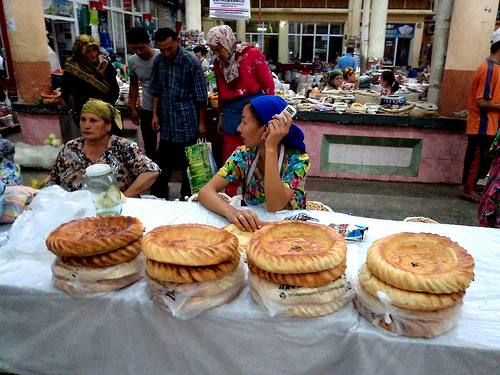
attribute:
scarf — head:
[254, 153, 305, 183]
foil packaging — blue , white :
[282, 97, 398, 149]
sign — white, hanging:
[207, 0, 249, 20]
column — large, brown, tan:
[12, 0, 91, 115]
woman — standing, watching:
[60, 35, 120, 137]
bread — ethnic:
[48, 217, 474, 340]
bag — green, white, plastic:
[175, 65, 198, 109]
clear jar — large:
[84, 164, 123, 216]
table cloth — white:
[1, 182, 498, 372]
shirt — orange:
[462, 62, 499, 144]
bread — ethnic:
[140, 222, 240, 266]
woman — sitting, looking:
[36, 95, 168, 197]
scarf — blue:
[248, 91, 313, 135]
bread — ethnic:
[44, 212, 146, 294]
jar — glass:
[80, 162, 121, 216]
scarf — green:
[80, 97, 122, 130]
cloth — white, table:
[20, 153, 498, 343]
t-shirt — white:
[124, 49, 157, 113]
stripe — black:
[136, 71, 154, 85]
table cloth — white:
[13, 159, 498, 373]